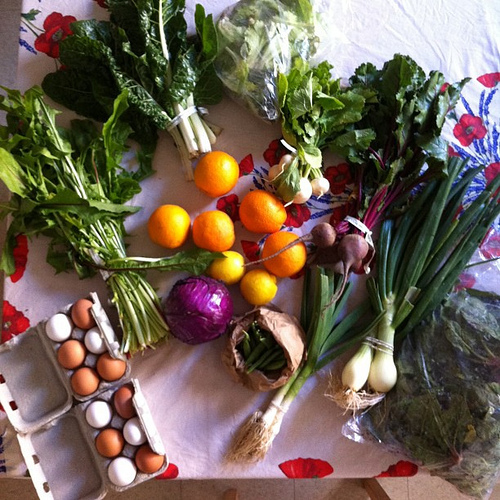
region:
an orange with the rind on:
[188, 147, 244, 200]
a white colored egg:
[38, 307, 80, 342]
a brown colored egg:
[53, 335, 90, 372]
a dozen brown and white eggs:
[42, 291, 170, 490]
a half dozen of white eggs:
[36, 286, 176, 493]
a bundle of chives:
[332, 146, 499, 424]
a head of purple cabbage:
[158, 271, 242, 351]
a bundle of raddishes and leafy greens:
[235, 51, 472, 306]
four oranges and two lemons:
[140, 141, 320, 310]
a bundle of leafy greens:
[37, 0, 235, 185]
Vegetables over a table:
[0, 8, 498, 493]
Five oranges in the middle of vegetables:
[141, 127, 312, 279]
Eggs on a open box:
[0, 285, 188, 492]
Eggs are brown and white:
[45, 291, 169, 493]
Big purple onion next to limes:
[155, 260, 242, 350]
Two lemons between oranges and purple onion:
[202, 247, 284, 304]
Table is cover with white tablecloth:
[0, 0, 490, 484]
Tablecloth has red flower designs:
[7, 5, 492, 492]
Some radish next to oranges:
[311, 211, 373, 281]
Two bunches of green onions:
[228, 162, 468, 467]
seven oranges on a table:
[140, 141, 314, 306]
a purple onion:
[158, 266, 236, 357]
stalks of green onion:
[335, 153, 496, 410]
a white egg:
[41, 311, 75, 342]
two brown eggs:
[67, 350, 127, 398]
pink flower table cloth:
[431, 60, 498, 238]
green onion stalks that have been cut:
[1, 66, 178, 344]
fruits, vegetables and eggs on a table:
[0, 7, 495, 497]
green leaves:
[0, 93, 161, 233]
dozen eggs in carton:
[35, 286, 202, 498]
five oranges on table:
[150, 135, 322, 277]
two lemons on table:
[206, 238, 312, 323]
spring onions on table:
[320, 128, 499, 428]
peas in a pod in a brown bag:
[213, 284, 327, 414]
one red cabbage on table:
[158, 260, 251, 377]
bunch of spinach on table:
[55, 44, 270, 175]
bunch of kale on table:
[1, 64, 183, 367]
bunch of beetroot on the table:
[272, 20, 476, 282]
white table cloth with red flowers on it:
[6, 88, 498, 498]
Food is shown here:
[55, 148, 444, 433]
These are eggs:
[18, 311, 195, 480]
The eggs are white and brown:
[40, 319, 175, 441]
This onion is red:
[156, 264, 273, 380]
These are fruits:
[165, 157, 352, 294]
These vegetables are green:
[391, 68, 490, 275]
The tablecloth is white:
[171, 372, 406, 498]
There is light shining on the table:
[325, 13, 499, 128]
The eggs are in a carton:
[26, 317, 185, 454]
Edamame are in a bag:
[209, 312, 344, 388]